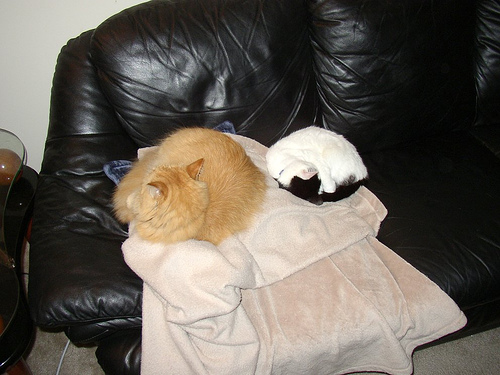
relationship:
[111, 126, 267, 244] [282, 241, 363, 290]
cat on blanket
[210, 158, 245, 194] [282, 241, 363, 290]
tan cat on blanket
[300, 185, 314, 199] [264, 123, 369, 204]
black and white cat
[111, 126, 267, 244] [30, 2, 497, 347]
cat on leather couch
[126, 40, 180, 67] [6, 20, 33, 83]
black lear on wall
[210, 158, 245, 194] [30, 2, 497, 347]
tan blanket on couch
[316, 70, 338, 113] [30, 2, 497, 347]
wrinkles on black couch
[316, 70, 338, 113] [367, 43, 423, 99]
wrinkles on leather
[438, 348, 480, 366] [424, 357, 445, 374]
gray carpet on floor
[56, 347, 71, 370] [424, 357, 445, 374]
cord on floor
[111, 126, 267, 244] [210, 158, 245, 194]
cat curled up and tan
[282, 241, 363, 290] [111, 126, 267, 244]
blanket under cat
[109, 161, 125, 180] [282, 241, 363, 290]
jeans under blanket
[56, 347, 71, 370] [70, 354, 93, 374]
cord on carpet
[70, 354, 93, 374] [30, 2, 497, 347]
carpet on couch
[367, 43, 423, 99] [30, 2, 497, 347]
leather on couch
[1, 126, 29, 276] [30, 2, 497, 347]
guitar next to couch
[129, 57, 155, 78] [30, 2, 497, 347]
light reflecting on couch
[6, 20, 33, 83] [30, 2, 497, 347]
wall behind couch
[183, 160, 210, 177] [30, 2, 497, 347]
ear of couch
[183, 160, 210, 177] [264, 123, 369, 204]
ear of cat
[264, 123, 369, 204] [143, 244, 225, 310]
cat sleep on pillow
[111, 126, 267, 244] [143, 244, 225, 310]
cat sleeping on a pillow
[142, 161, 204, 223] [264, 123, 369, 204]
head of a cat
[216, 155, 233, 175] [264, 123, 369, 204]
fur of a cat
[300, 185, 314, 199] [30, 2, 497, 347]
black leather couch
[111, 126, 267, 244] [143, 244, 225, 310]
cat sleep on a pillow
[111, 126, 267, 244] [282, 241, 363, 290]
cat sleeping on a blanket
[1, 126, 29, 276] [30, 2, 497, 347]
guitar near couch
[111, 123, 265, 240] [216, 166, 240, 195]
cat fluffy and orange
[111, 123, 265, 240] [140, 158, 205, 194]
cat has ears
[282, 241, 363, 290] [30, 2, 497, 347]
blanket on black couch